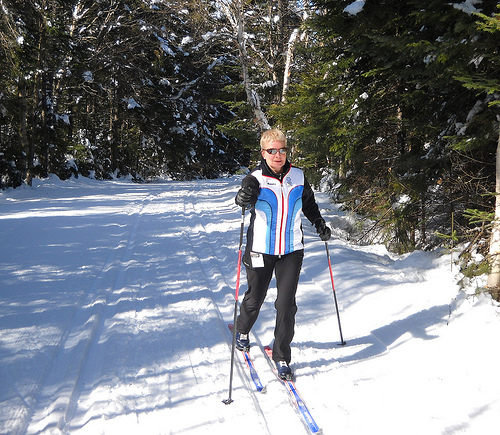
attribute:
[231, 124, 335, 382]
woman — skiing, walking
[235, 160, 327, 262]
coat — white, blue, red, black, blue striped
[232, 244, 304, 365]
pant — black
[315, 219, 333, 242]
gloves — black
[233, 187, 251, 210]
gloves — black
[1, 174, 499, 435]
snow — white, full, ground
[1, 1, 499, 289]
trees — covered, green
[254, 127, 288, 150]
hair — brown, blonde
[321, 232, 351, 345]
stick — thin, red, black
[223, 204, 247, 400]
stick — thin, red, black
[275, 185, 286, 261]
zipper — red